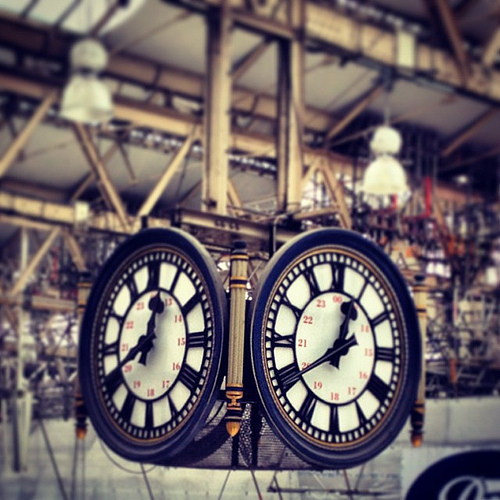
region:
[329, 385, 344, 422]
number 18 is written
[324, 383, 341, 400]
number 18 is written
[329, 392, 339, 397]
number 18 is written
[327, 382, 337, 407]
number 18 is written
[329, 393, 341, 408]
number 18 is written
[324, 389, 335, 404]
number 18 is written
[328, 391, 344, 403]
number 18 is written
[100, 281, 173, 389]
Hand of a clock.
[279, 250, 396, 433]
Number in roman numerial.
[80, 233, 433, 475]
A pair of clocks.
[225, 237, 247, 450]
A column for the clock.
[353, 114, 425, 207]
A light hanging down.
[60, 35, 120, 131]
The light is off.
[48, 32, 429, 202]
Lights on the ceiling.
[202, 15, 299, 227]
Beams on the ceiling.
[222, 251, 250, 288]
Bands on the column.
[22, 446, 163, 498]
Wires hanging down from rafters.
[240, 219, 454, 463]
The clock is white and black.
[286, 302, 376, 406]
The hands are black.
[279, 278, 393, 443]
The seconds are red.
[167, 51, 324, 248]
The poles are metal.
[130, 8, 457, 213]
The poles are brown.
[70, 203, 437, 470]
Two clocks are showing.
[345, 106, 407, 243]
White objects are hanging.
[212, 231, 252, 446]
The pillar is in the middle of the clocks.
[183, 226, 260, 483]
The pillar is brown and gold.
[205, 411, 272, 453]
The tip is gold.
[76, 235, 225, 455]
a black and white clock face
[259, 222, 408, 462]
a black and white clock face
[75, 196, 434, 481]
an ornate multi-faced clock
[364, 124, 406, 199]
overhead lighting with white shade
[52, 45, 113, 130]
overhead lighting with white shade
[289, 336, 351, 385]
black minute hand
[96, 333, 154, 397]
black minute hand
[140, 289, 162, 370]
short black hour hand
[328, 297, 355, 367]
short black hour hand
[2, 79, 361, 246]
metal cross beams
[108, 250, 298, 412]
the clocks are visible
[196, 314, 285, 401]
the clocks are visible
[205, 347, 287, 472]
the clocks are visible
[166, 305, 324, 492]
the clocks are visible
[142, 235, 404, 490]
the clocks are visible